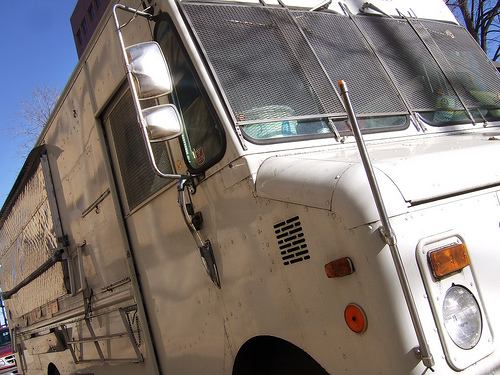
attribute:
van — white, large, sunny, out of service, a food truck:
[0, 0, 499, 373]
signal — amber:
[322, 257, 353, 279]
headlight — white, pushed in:
[440, 284, 482, 351]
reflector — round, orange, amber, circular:
[343, 301, 367, 337]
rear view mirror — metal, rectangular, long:
[122, 41, 175, 101]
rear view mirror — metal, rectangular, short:
[139, 103, 185, 143]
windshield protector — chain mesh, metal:
[177, 0, 499, 128]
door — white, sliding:
[99, 90, 226, 374]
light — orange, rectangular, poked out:
[427, 242, 472, 282]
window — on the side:
[153, 17, 223, 172]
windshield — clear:
[188, 1, 409, 142]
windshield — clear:
[359, 17, 499, 126]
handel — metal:
[174, 175, 222, 289]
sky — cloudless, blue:
[1, 2, 499, 212]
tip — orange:
[337, 78, 345, 85]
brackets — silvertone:
[380, 226, 397, 247]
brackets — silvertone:
[415, 346, 430, 357]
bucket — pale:
[239, 105, 299, 139]